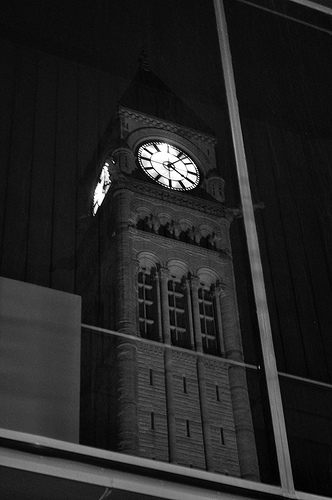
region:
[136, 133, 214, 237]
White face on clock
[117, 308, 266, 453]
Tall stone clock tower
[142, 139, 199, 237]
Black numbers on clock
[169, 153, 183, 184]
Black hands on clock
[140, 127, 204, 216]
Face of clock has light shining inside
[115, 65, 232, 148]
Black roof on clock tower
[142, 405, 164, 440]
Tiny slit window on tower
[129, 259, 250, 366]
Large windows on clock tower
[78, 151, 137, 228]
Lite up face on clock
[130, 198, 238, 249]
Arches near top of clock tower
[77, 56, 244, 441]
this is a building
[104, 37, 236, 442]
the building is tall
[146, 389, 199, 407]
the building is made of stone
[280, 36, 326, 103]
this is the sky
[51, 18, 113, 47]
the sky is clear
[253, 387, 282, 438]
this is a window pane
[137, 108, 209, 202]
this is a clock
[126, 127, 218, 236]
the clock is on the building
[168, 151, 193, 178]
the time is seven minutes past four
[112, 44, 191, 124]
the building top is pointed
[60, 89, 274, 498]
Tower of building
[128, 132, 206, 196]
Clock is white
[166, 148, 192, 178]
Hands of clock are black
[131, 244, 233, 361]
Windows in front of tower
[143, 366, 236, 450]
Small rectangle openings in tower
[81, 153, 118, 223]
Clock in lateral side is white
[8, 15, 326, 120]
Sky is dark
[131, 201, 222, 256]
Four windows under front clock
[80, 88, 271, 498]
Tower is made of stone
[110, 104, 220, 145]
Intricate decorations on top of tower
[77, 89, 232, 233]
clocks on top of tower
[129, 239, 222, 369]
arches on top of divided panels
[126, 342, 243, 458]
narrow openings on separate columns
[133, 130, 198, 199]
clock lit from within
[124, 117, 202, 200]
both hands on one side of the clock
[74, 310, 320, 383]
horizontal bar in front of tower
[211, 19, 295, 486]
long vertical pole in front of tower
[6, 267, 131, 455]
blank surface near tower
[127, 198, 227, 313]
smaller arches above larger ones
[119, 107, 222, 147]
repeating pattern on top of tower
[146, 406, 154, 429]
a small slit in the wall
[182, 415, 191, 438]
a small slit in the wall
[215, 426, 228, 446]
a small slit in the wall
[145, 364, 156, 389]
a small slit in the wall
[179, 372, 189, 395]
a small slit in the wall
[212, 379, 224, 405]
a small slit in the wall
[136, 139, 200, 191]
clock on a tower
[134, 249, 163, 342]
a tall arched window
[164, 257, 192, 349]
a tall arched window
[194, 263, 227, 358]
a tall arched window